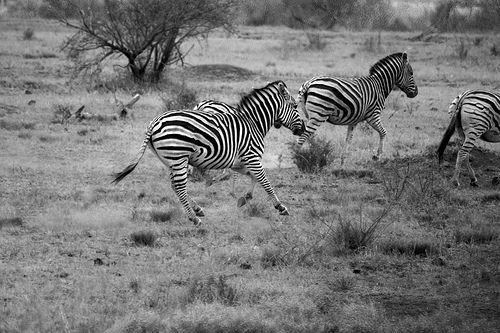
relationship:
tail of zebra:
[111, 133, 152, 185] [111, 76, 309, 229]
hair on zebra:
[238, 79, 279, 108] [111, 76, 309, 229]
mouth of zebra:
[405, 84, 421, 103] [298, 49, 420, 163]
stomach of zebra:
[332, 103, 370, 125] [300, 58, 421, 159]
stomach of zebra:
[192, 150, 246, 167] [108, 82, 317, 219]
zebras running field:
[151, 69, 368, 200] [5, 26, 495, 325]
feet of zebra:
[173, 197, 210, 227] [111, 76, 309, 229]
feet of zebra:
[271, 197, 293, 220] [111, 76, 309, 229]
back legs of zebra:
[166, 167, 206, 226] [111, 76, 309, 229]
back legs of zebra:
[293, 112, 320, 170] [111, 76, 309, 229]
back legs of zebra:
[449, 130, 483, 193] [436, 87, 498, 187]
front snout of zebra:
[368, 46, 410, 81] [300, 41, 415, 174]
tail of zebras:
[113, 135, 157, 189] [114, 77, 304, 218]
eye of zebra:
[405, 67, 418, 76] [361, 52, 400, 102]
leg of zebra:
[367, 109, 385, 163] [298, 49, 420, 163]